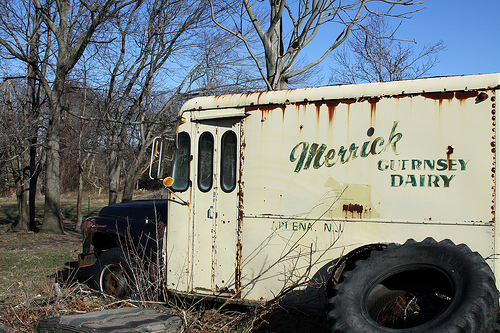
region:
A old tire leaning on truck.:
[320, 233, 482, 331]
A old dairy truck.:
[90, 90, 498, 293]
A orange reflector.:
[153, 168, 178, 193]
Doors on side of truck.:
[189, 121, 246, 298]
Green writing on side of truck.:
[276, 127, 468, 196]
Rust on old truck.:
[245, 87, 478, 104]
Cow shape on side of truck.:
[315, 173, 384, 213]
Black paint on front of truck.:
[64, 191, 179, 293]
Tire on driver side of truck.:
[87, 248, 145, 307]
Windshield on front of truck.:
[170, 137, 190, 188]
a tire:
[350, 253, 481, 330]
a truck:
[48, 87, 488, 317]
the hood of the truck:
[117, 196, 168, 213]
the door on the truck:
[189, 138, 238, 282]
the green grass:
[13, 237, 63, 279]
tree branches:
[5, 10, 73, 82]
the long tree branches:
[365, 37, 436, 74]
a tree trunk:
[42, 172, 74, 227]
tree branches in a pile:
[191, 295, 243, 325]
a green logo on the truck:
[282, 125, 467, 197]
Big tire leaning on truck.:
[328, 235, 490, 330]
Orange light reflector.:
[161, 170, 177, 190]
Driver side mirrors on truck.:
[143, 132, 177, 185]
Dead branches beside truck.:
[121, 266, 328, 331]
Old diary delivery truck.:
[77, 95, 467, 298]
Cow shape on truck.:
[321, 174, 379, 218]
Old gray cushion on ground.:
[32, 303, 186, 331]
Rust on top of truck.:
[245, 86, 492, 111]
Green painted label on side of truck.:
[272, 122, 460, 194]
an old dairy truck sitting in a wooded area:
[6, 5, 485, 326]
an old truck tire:
[321, 229, 489, 324]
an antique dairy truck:
[65, 85, 482, 310]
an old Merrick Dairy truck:
[48, 59, 470, 262]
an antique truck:
[55, 57, 476, 285]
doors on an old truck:
[151, 80, 296, 310]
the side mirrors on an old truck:
[133, 112, 179, 209]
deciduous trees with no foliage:
[3, 0, 146, 269]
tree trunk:
[34, 158, 69, 246]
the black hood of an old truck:
[65, 185, 178, 312]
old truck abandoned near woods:
[46, 62, 458, 297]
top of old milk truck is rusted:
[172, 76, 489, 132]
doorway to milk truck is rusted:
[166, 92, 259, 299]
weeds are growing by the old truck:
[115, 215, 306, 320]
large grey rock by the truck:
[40, 290, 195, 323]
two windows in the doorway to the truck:
[190, 120, 250, 198]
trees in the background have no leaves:
[10, 5, 190, 178]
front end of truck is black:
[60, 191, 180, 297]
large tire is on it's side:
[307, 236, 489, 326]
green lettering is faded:
[283, 118, 470, 197]